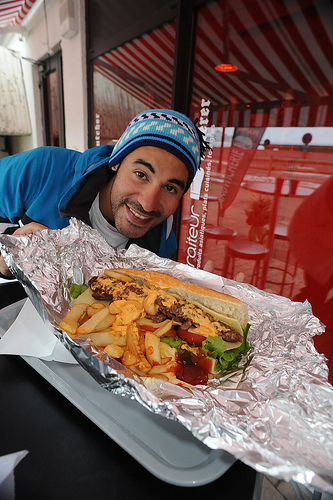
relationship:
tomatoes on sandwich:
[143, 322, 208, 348] [76, 262, 249, 377]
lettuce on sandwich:
[70, 281, 254, 371] [76, 262, 249, 377]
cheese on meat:
[97, 276, 228, 356] [86, 275, 260, 343]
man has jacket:
[0, 107, 200, 280] [0, 146, 176, 258]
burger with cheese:
[59, 267, 251, 388] [105, 286, 156, 325]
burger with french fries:
[59, 267, 251, 388] [60, 298, 194, 389]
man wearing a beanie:
[0, 107, 200, 280] [108, 107, 200, 195]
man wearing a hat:
[1, 105, 213, 286] [101, 104, 201, 172]